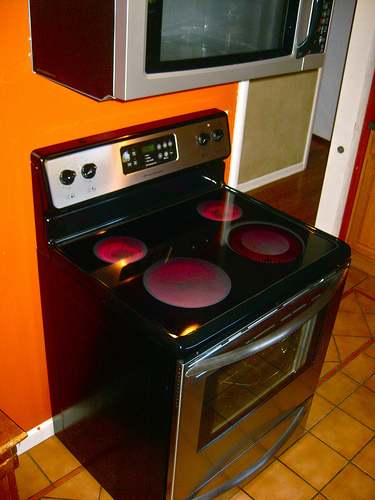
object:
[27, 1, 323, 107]
microwave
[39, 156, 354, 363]
surface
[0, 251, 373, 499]
floor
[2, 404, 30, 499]
table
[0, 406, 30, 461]
corner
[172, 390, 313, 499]
drawer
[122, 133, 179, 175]
console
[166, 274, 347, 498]
door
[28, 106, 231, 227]
panel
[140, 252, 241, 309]
burner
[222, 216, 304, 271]
burner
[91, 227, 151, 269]
burner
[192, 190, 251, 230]
burner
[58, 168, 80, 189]
knob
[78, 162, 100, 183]
knob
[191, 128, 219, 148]
knob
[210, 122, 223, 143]
knob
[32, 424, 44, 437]
paint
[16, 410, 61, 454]
baseboard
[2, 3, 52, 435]
wall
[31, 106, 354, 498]
oven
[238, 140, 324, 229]
floor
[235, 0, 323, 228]
hallway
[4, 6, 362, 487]
kitchen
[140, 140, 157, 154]
clock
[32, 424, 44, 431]
spot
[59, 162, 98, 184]
dials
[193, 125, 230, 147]
dials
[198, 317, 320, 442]
window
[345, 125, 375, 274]
cabinet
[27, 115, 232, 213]
display